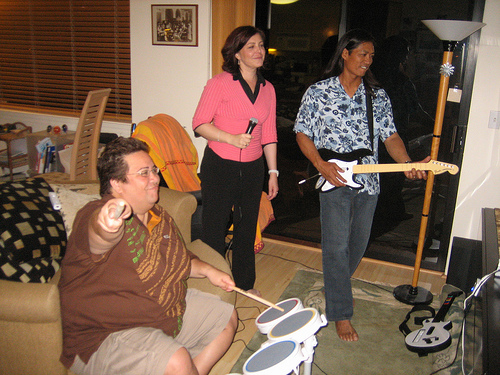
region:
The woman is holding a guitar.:
[296, 28, 456, 351]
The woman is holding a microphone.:
[180, 19, 285, 296]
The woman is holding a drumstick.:
[43, 123, 283, 372]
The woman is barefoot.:
[289, 28, 464, 348]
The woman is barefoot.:
[191, 20, 285, 305]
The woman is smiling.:
[298, 23, 466, 349]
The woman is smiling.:
[188, 25, 283, 305]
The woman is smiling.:
[53, 120, 243, 373]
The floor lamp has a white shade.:
[394, 13, 486, 325]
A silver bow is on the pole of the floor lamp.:
[391, 3, 490, 321]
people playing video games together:
[54, 24, 428, 374]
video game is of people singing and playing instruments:
[54, 25, 414, 374]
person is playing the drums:
[61, 133, 323, 374]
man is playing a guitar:
[294, 28, 459, 343]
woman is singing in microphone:
[193, 23, 277, 298]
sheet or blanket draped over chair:
[130, 114, 275, 254]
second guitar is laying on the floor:
[395, 288, 461, 356]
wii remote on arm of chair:
[50, 188, 60, 210]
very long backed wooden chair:
[22, 85, 110, 184]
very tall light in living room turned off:
[392, 18, 484, 303]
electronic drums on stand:
[242, 293, 327, 373]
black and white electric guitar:
[306, 145, 459, 199]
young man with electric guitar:
[300, 27, 431, 342]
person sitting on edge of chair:
[60, 137, 243, 369]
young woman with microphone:
[189, 25, 279, 297]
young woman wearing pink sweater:
[188, 20, 285, 292]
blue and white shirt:
[293, 75, 398, 199]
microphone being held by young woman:
[237, 116, 259, 155]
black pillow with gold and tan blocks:
[2, 173, 69, 287]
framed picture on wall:
[151, 3, 201, 50]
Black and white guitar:
[306, 148, 371, 192]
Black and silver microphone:
[241, 114, 258, 134]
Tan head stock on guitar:
[353, 159, 457, 174]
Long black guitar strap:
[364, 82, 376, 149]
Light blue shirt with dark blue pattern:
[299, 78, 391, 142]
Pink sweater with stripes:
[198, 70, 273, 153]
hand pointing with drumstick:
[93, 201, 130, 238]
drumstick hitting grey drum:
[221, 281, 293, 311]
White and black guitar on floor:
[406, 287, 459, 353]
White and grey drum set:
[247, 301, 322, 371]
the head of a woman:
[96, 130, 164, 209]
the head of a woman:
[219, 27, 270, 70]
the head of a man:
[333, 30, 376, 76]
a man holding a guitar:
[294, 35, 459, 208]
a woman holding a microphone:
[193, 29, 286, 168]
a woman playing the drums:
[91, 134, 326, 370]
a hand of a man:
[317, 155, 348, 193]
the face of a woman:
[246, 40, 266, 67]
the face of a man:
[351, 43, 373, 77]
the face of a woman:
[131, 157, 166, 202]